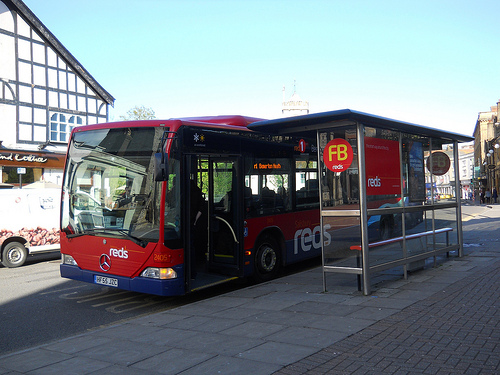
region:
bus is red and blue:
[51, 119, 471, 294]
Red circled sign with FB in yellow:
[311, 135, 361, 177]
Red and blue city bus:
[47, 115, 318, 299]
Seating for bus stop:
[255, 99, 485, 305]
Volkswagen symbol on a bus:
[87, 252, 129, 279]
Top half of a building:
[0, 0, 141, 145]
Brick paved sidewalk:
[287, 271, 498, 373]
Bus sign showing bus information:
[244, 154, 306, 175]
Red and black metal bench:
[346, 227, 473, 269]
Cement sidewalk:
[28, 285, 383, 370]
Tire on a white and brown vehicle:
[0, 237, 44, 271]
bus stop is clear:
[247, 82, 471, 316]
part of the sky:
[313, 7, 395, 80]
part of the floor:
[394, 302, 444, 357]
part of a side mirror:
[146, 162, 173, 195]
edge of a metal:
[351, 220, 374, 277]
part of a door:
[185, 213, 224, 274]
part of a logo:
[94, 250, 115, 273]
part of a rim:
[251, 242, 288, 290]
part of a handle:
[160, 130, 182, 153]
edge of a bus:
[151, 287, 188, 304]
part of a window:
[91, 164, 161, 232]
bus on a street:
[42, 106, 431, 307]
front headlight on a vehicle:
[132, 261, 184, 291]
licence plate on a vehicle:
[84, 271, 124, 291]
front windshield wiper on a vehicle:
[86, 221, 151, 251]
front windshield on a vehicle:
[47, 118, 187, 254]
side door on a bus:
[179, 123, 251, 305]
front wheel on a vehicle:
[244, 220, 296, 292]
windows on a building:
[42, 104, 87, 148]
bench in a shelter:
[339, 222, 456, 297]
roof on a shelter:
[240, 97, 482, 162]